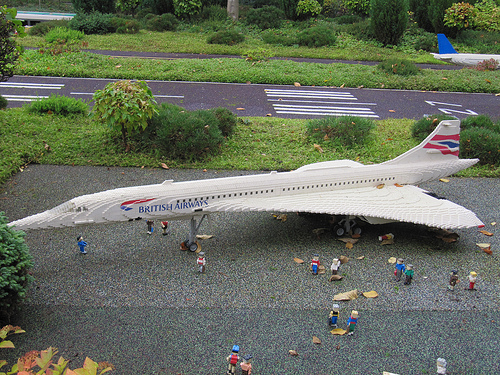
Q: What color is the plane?
A: White.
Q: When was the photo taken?
A: Daytime.